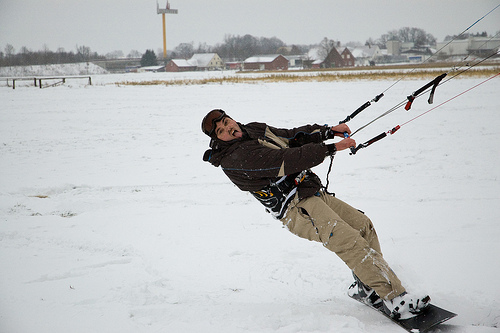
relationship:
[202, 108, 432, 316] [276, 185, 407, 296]
man with pants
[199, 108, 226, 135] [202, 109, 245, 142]
eyewear on head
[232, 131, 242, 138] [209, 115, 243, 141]
tongue in face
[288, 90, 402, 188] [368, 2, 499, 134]
harness with wire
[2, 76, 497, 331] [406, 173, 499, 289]
field of snow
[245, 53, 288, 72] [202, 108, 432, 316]
building behind man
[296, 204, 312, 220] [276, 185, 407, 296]
pocket on pants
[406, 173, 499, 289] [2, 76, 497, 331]
snow on field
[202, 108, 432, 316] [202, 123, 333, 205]
man with coat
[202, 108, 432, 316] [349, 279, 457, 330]
man on board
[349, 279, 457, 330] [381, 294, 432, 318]
board near feet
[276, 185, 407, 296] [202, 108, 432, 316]
pants on man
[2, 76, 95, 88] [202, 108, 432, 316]
fence behind man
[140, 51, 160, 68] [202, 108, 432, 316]
tree behind man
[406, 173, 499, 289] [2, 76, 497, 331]
snow in field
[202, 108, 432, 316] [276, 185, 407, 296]
man in pants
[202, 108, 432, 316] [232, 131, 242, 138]
man with tongue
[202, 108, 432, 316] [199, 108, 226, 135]
man with eyewear